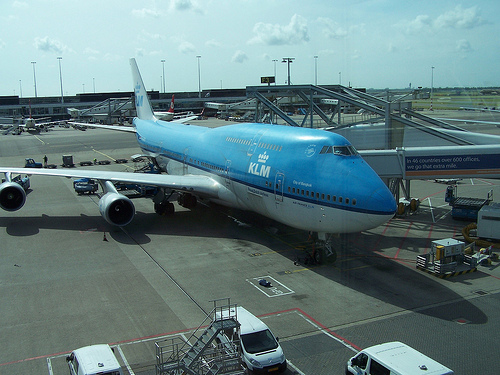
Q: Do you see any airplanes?
A: Yes, there is an airplane.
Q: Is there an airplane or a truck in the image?
A: Yes, there is an airplane.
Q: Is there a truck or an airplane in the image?
A: Yes, there is an airplane.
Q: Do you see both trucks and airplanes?
A: No, there is an airplane but no trucks.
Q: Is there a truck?
A: No, there are no trucks.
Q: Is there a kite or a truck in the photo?
A: No, there are no trucks or kites.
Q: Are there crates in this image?
A: No, there are no crates.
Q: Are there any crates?
A: No, there are no crates.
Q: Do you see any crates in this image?
A: No, there are no crates.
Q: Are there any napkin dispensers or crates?
A: No, there are no crates or napkin dispensers.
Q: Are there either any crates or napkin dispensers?
A: No, there are no crates or napkin dispensers.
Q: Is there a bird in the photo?
A: No, there are no birds.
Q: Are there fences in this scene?
A: No, there are no fences.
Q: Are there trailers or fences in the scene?
A: No, there are no fences or trailers.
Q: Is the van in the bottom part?
A: Yes, the van is in the bottom of the image.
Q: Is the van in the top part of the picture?
A: No, the van is in the bottom of the image.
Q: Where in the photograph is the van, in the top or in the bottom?
A: The van is in the bottom of the image.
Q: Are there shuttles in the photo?
A: No, there are no shuttles.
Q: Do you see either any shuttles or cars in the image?
A: No, there are no shuttles or cars.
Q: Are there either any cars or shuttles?
A: No, there are no shuttles or cars.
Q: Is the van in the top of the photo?
A: No, the van is in the bottom of the image.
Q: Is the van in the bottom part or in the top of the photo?
A: The van is in the bottom of the image.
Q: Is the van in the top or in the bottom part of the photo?
A: The van is in the bottom of the image.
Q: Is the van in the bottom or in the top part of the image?
A: The van is in the bottom of the image.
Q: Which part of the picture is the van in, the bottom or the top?
A: The van is in the bottom of the image.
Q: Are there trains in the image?
A: No, there are no trains.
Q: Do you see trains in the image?
A: No, there are no trains.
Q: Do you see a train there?
A: No, there are no trains.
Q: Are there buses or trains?
A: No, there are no trains or buses.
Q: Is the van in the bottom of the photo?
A: Yes, the van is in the bottom of the image.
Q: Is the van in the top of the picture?
A: No, the van is in the bottom of the image.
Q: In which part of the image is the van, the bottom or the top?
A: The van is in the bottom of the image.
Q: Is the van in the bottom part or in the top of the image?
A: The van is in the bottom of the image.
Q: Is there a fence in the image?
A: No, there are no fences.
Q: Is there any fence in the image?
A: No, there are no fences.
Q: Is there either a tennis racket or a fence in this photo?
A: No, there are no fences or rackets.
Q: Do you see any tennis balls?
A: No, there are no tennis balls.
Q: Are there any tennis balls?
A: No, there are no tennis balls.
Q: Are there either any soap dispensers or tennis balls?
A: No, there are no tennis balls or soap dispensers.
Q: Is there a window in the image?
A: Yes, there are windows.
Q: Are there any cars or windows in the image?
A: Yes, there are windows.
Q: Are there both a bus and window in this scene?
A: No, there are windows but no buses.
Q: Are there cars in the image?
A: No, there are no cars.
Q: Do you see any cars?
A: No, there are no cars.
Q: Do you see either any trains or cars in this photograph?
A: No, there are no cars or trains.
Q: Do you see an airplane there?
A: Yes, there is an airplane.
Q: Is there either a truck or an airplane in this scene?
A: Yes, there is an airplane.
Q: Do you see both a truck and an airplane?
A: No, there is an airplane but no trucks.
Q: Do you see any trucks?
A: No, there are no trucks.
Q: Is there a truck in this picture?
A: No, there are no trucks.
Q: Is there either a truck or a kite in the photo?
A: No, there are no trucks or kites.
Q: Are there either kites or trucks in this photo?
A: No, there are no trucks or kites.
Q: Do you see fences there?
A: No, there are no fences.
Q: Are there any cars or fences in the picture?
A: No, there are no fences or cars.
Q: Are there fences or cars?
A: No, there are no fences or cars.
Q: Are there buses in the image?
A: No, there are no buses.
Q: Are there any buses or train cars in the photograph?
A: No, there are no buses or train cars.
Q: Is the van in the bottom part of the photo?
A: Yes, the van is in the bottom of the image.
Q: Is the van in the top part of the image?
A: No, the van is in the bottom of the image.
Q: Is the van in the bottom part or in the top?
A: The van is in the bottom of the image.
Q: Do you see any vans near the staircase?
A: Yes, there is a van near the staircase.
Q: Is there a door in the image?
A: Yes, there is a door.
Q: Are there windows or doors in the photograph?
A: Yes, there is a door.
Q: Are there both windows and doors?
A: Yes, there are both a door and windows.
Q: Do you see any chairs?
A: No, there are no chairs.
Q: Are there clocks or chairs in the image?
A: No, there are no chairs or clocks.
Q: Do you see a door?
A: Yes, there is a door.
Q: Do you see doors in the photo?
A: Yes, there is a door.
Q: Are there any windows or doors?
A: Yes, there is a door.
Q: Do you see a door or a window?
A: Yes, there is a door.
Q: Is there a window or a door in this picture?
A: Yes, there is a door.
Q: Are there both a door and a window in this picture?
A: Yes, there are both a door and a window.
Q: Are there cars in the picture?
A: No, there are no cars.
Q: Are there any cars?
A: No, there are no cars.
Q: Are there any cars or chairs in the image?
A: No, there are no cars or chairs.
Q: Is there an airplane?
A: Yes, there is an airplane.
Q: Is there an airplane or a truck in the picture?
A: Yes, there is an airplane.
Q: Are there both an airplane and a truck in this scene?
A: No, there is an airplane but no trucks.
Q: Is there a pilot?
A: No, there are no pilots.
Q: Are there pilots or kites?
A: No, there are no pilots or kites.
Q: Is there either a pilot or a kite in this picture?
A: No, there are no pilots or kites.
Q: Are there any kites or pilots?
A: No, there are no pilots or kites.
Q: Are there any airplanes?
A: Yes, there is an airplane.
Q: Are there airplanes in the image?
A: Yes, there is an airplane.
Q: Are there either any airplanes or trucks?
A: Yes, there is an airplane.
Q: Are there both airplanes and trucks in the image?
A: No, there is an airplane but no trucks.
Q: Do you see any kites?
A: No, there are no kites.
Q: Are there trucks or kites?
A: No, there are no kites or trucks.